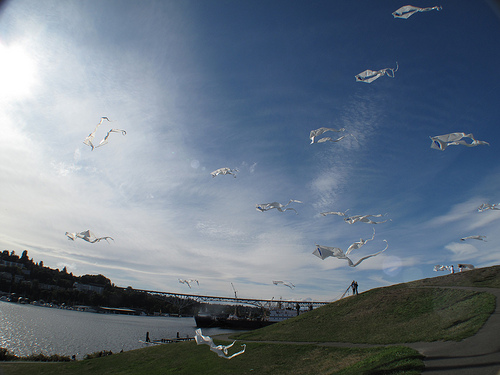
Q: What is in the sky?
A: Kites.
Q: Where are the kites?
A: Sky.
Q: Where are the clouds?
A: Sky.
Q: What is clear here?
A: The sky.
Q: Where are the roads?
A: On the hill.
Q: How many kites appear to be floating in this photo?
A: 16.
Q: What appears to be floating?
A: Kites.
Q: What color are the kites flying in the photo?
A: White.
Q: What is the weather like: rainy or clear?
A: Clear.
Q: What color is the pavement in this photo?
A: Gray.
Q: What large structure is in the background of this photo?
A: A bridge.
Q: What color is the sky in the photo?
A: Blue.